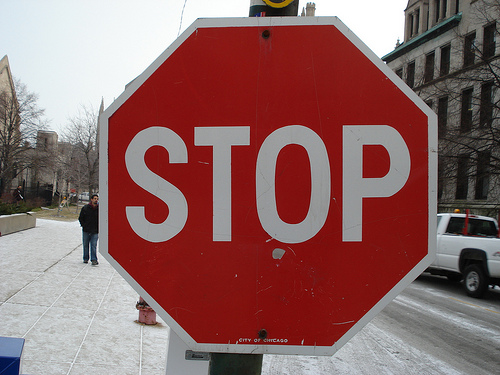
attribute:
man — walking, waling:
[75, 187, 98, 263]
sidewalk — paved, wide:
[19, 228, 116, 341]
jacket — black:
[78, 205, 104, 232]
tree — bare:
[55, 124, 102, 214]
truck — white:
[420, 204, 498, 308]